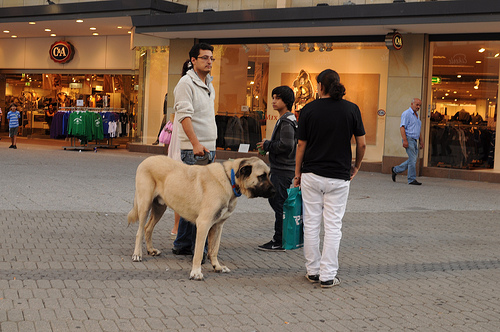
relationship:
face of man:
[189, 48, 215, 75] [170, 38, 221, 254]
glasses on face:
[196, 51, 215, 66] [189, 48, 215, 75]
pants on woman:
[285, 169, 367, 285] [291, 67, 365, 288]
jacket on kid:
[264, 112, 302, 169] [267, 70, 301, 252]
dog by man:
[126, 153, 276, 280] [170, 38, 221, 257]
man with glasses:
[170, 38, 221, 257] [191, 54, 214, 66]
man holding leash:
[170, 38, 221, 257] [200, 146, 240, 199]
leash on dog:
[200, 146, 240, 199] [126, 153, 276, 280]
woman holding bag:
[291, 67, 365, 288] [280, 185, 302, 251]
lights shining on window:
[189, 37, 387, 51] [217, 47, 267, 119]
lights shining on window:
[0, 22, 134, 43] [69, 71, 131, 128]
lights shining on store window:
[472, 44, 498, 69] [429, 40, 494, 169]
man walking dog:
[170, 38, 221, 257] [126, 153, 276, 280]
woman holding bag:
[289, 63, 376, 290] [279, 182, 301, 261]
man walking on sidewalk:
[388, 93, 425, 188] [0, 144, 500, 332]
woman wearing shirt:
[289, 63, 376, 290] [292, 93, 366, 183]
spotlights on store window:
[238, 38, 333, 55] [208, 39, 385, 161]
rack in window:
[213, 110, 265, 151] [218, 44, 278, 166]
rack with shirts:
[47, 109, 128, 155] [66, 106, 136, 138]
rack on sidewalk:
[47, 109, 128, 155] [0, 144, 500, 332]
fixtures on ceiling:
[7, 12, 129, 52] [0, 12, 135, 40]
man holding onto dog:
[170, 38, 221, 257] [126, 153, 276, 280]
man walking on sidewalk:
[170, 38, 221, 254] [6, 135, 496, 330]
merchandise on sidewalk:
[44, 104, 165, 142] [4, 151, 483, 316]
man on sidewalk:
[391, 97, 424, 186] [0, 170, 500, 326]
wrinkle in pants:
[323, 200, 340, 208] [297, 165, 350, 288]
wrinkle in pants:
[325, 209, 340, 215] [297, 165, 350, 288]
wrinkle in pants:
[322, 214, 334, 224] [297, 165, 350, 288]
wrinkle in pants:
[324, 226, 334, 230] [297, 165, 350, 288]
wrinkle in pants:
[324, 227, 341, 238] [297, 165, 350, 288]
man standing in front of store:
[4, 100, 24, 150] [4, 35, 141, 144]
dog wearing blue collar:
[126, 153, 276, 280] [223, 155, 240, 199]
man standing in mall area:
[170, 38, 221, 257] [4, 146, 497, 328]